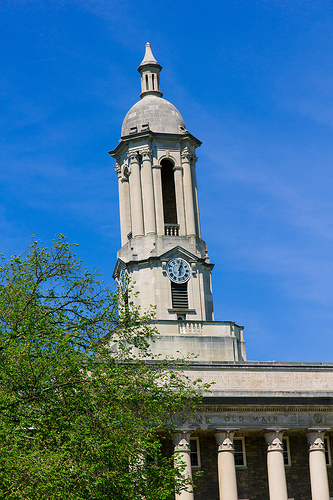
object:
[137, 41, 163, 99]
part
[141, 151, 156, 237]
pillar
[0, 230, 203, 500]
trees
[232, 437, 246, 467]
windows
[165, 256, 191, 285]
clock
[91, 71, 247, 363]
tower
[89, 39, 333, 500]
building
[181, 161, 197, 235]
column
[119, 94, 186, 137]
dome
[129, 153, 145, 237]
columns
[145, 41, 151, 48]
top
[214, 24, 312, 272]
sky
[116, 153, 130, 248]
pillars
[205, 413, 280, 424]
words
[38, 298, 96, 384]
leaves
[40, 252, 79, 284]
branches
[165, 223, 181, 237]
platform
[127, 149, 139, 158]
detailing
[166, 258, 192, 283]
face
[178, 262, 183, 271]
hands